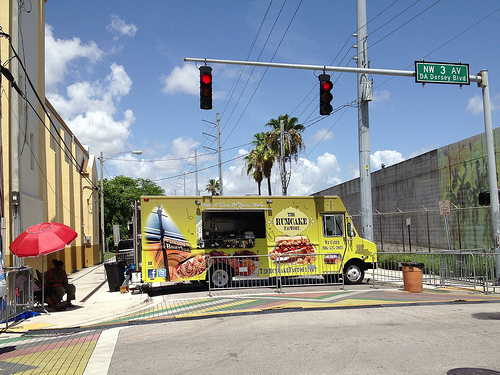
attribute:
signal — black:
[199, 68, 212, 110]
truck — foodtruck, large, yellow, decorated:
[135, 196, 378, 288]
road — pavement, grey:
[1, 288, 498, 375]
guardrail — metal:
[209, 254, 346, 290]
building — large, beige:
[2, 0, 104, 286]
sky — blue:
[43, 1, 500, 195]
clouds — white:
[42, 24, 134, 158]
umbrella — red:
[7, 222, 77, 259]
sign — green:
[415, 62, 470, 83]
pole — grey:
[356, 0, 374, 247]